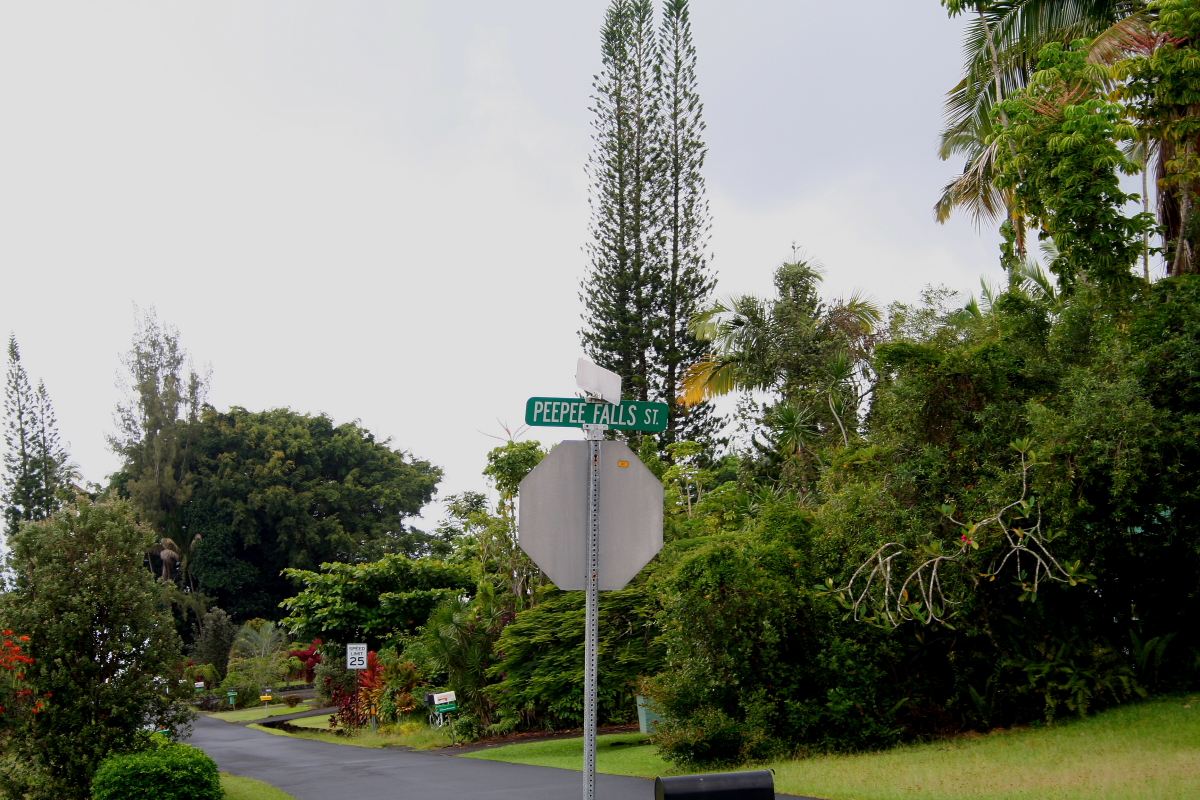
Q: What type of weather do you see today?
A: It is cloudy.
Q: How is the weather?
A: It is cloudy.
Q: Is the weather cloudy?
A: Yes, it is cloudy.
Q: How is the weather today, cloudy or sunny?
A: It is cloudy.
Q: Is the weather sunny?
A: No, it is cloudy.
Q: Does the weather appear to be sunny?
A: No, it is cloudy.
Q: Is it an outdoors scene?
A: Yes, it is outdoors.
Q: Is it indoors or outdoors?
A: It is outdoors.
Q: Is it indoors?
A: No, it is outdoors.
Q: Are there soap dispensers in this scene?
A: No, there are no soap dispensers.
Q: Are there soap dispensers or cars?
A: No, there are no soap dispensers or cars.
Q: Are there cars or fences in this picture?
A: No, there are no cars or fences.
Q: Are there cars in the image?
A: No, there are no cars.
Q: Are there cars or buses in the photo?
A: No, there are no cars or buses.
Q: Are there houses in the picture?
A: No, there are no houses.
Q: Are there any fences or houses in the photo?
A: No, there are no houses or fences.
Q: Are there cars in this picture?
A: No, there are no cars.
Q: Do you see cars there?
A: No, there are no cars.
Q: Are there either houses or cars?
A: No, there are no cars or houses.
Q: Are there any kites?
A: No, there are no kites.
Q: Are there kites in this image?
A: No, there are no kites.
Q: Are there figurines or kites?
A: No, there are no kites or figurines.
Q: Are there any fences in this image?
A: No, there are no fences.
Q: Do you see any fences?
A: No, there are no fences.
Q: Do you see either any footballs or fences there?
A: No, there are no fences or footballs.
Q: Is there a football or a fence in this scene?
A: No, there are no fences or footballs.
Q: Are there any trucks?
A: No, there are no trucks.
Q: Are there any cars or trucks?
A: No, there are no trucks or cars.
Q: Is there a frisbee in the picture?
A: No, there are no frisbees.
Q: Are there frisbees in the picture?
A: No, there are no frisbees.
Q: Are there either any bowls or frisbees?
A: No, there are no frisbees or bowls.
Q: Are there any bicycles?
A: No, there are no bicycles.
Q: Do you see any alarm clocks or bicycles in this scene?
A: No, there are no bicycles or alarm clocks.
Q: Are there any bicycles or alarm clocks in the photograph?
A: No, there are no bicycles or alarm clocks.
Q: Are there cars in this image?
A: No, there are no cars.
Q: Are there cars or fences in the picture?
A: No, there are no cars or fences.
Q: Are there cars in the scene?
A: No, there are no cars.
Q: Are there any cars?
A: No, there are no cars.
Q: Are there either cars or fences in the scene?
A: No, there are no cars or fences.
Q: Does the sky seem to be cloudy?
A: Yes, the sky is cloudy.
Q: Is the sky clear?
A: No, the sky is cloudy.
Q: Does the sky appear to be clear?
A: No, the sky is cloudy.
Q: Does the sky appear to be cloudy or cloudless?
A: The sky is cloudy.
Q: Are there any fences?
A: No, there are no fences.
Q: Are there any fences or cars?
A: No, there are no fences or cars.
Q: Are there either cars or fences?
A: No, there are no fences or cars.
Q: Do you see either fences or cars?
A: No, there are no fences or cars.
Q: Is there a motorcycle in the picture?
A: No, there are no motorcycles.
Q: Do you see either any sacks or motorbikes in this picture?
A: No, there are no motorbikes or sacks.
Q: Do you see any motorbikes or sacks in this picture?
A: No, there are no motorbikes or sacks.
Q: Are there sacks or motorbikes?
A: No, there are no motorbikes or sacks.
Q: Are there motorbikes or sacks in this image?
A: No, there are no motorbikes or sacks.